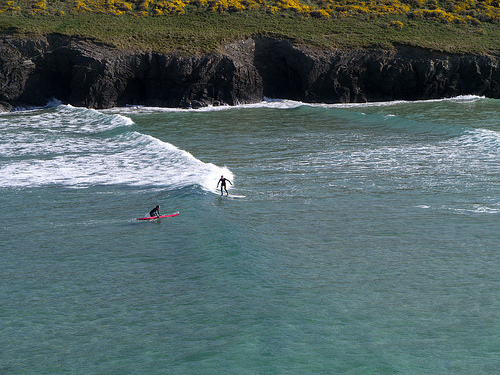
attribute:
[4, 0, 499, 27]
flowers — yellow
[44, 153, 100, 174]
wave — white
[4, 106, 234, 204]
wave — white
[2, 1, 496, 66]
grass — low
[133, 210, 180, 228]
surfboard — red